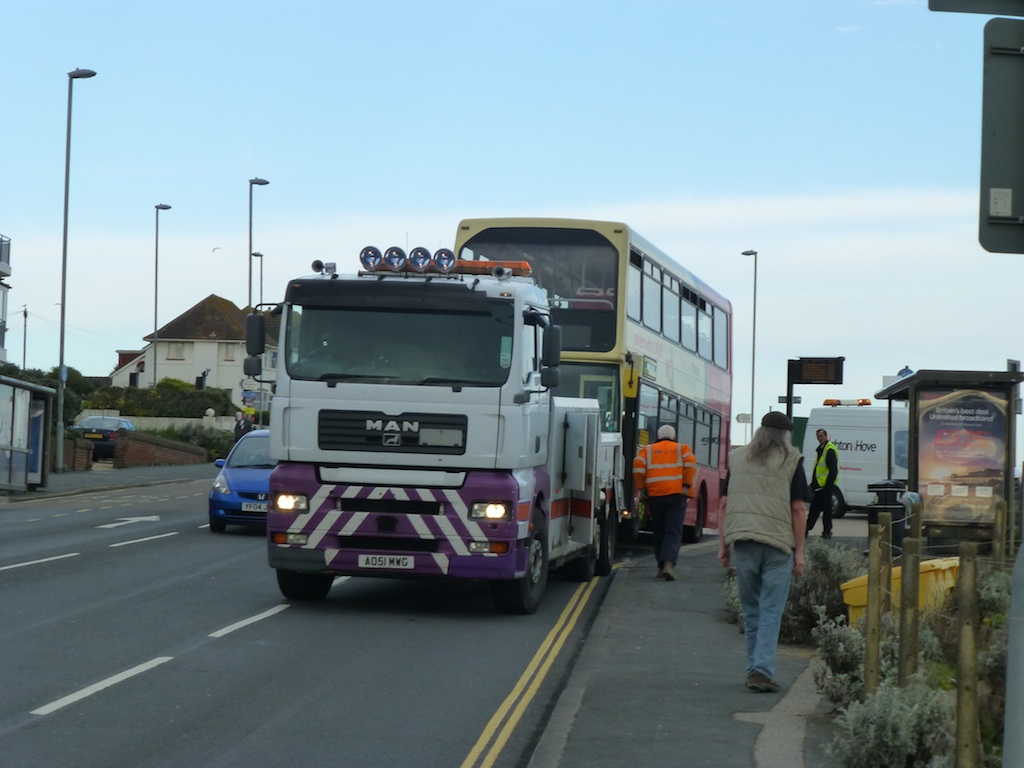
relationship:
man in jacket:
[634, 422, 695, 578] [634, 441, 696, 498]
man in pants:
[634, 422, 695, 578] [648, 493, 687, 571]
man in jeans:
[716, 411, 809, 691] [732, 545, 794, 686]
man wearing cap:
[715, 411, 808, 691] [760, 411, 795, 434]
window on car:
[229, 437, 281, 467] [208, 422, 277, 527]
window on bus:
[287, 292, 515, 385] [239, 248, 628, 616]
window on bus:
[458, 240, 617, 307] [454, 219, 733, 539]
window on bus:
[542, 308, 619, 351] [454, 219, 733, 539]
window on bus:
[549, 361, 620, 447] [454, 219, 733, 539]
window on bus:
[625, 267, 641, 324] [454, 219, 733, 539]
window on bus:
[641, 270, 661, 332] [454, 219, 733, 539]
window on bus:
[660, 282, 684, 343] [454, 219, 733, 539]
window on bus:
[679, 297, 699, 355] [454, 219, 733, 539]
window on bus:
[695, 307, 715, 364] [454, 219, 733, 539]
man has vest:
[634, 422, 695, 578] [644, 438, 684, 497]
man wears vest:
[805, 427, 841, 538] [811, 441, 840, 487]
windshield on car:
[226, 436, 280, 469] [205, 424, 276, 532]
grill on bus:
[310, 402, 463, 461] [240, 248, 629, 604]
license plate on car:
[240, 496, 278, 517] [208, 422, 278, 527]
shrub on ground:
[838, 684, 953, 765] [543, 531, 1006, 766]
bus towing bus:
[239, 248, 628, 616] [454, 218, 733, 538]